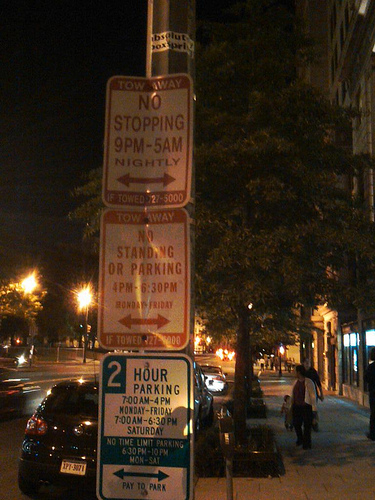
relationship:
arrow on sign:
[111, 465, 168, 489] [89, 344, 199, 491]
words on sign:
[105, 357, 185, 493] [88, 351, 196, 498]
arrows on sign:
[116, 311, 172, 330] [102, 202, 193, 352]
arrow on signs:
[111, 465, 168, 489] [100, 349, 191, 497]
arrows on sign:
[115, 167, 176, 188] [103, 73, 191, 211]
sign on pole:
[103, 73, 191, 211] [137, 3, 169, 356]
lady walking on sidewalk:
[283, 362, 323, 448] [254, 365, 369, 498]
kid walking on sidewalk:
[276, 391, 293, 431] [252, 355, 373, 496]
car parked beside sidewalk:
[16, 377, 98, 496] [194, 364, 374, 497]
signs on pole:
[100, 349, 191, 497] [124, 18, 193, 487]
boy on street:
[279, 393, 295, 432] [285, 407, 373, 471]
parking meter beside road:
[215, 403, 235, 497] [0, 353, 234, 497]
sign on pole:
[103, 73, 191, 211] [143, 0, 194, 357]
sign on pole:
[98, 213, 190, 349] [143, 0, 194, 357]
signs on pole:
[100, 349, 191, 497] [143, 0, 194, 357]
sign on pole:
[98, 213, 190, 349] [141, 2, 198, 77]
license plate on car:
[56, 457, 89, 477] [16, 359, 213, 491]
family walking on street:
[276, 353, 327, 451] [198, 361, 371, 494]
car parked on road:
[183, 355, 244, 405] [36, 357, 92, 396]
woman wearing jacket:
[283, 364, 324, 463] [287, 373, 330, 414]